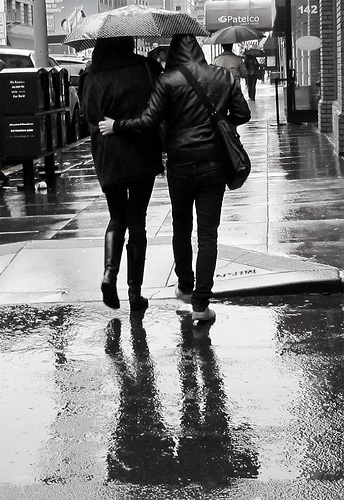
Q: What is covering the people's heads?
A: Umbrella.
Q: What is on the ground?
A: Rain water.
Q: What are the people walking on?
A: Sidewalk.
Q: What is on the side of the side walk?
A: Newspaper containers.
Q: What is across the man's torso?
A: Messenger bag.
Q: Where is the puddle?
A: In the street.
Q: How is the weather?
A: It is raining.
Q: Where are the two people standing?
A: Under an umbrella.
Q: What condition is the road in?
A: Wet.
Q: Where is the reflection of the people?
A: In the street.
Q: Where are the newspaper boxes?
A: On the left side of the sidewalk.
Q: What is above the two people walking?
A: An umbrella.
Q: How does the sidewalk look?
A: Wet.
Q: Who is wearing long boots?
A: The woman.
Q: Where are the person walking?
A: Road.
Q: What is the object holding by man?
A: Umbrella.